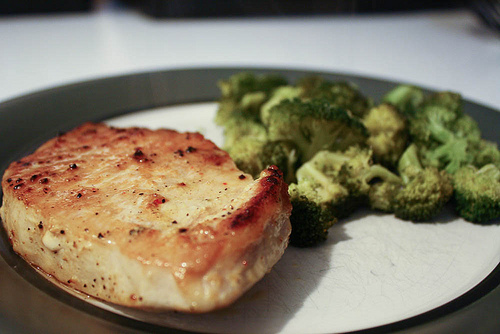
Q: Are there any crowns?
A: Yes, there is a crown.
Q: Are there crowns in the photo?
A: Yes, there is a crown.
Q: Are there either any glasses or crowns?
A: Yes, there is a crown.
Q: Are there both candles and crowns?
A: No, there is a crown but no candles.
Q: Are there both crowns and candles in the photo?
A: No, there is a crown but no candles.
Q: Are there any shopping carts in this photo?
A: No, there are no shopping carts.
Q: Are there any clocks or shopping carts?
A: No, there are no shopping carts or clocks.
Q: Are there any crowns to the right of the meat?
A: Yes, there is a crown to the right of the meat.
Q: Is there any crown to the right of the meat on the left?
A: Yes, there is a crown to the right of the meat.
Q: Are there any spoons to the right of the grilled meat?
A: No, there is a crown to the right of the meat.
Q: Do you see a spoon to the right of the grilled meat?
A: No, there is a crown to the right of the meat.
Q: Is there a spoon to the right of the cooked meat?
A: No, there is a crown to the right of the meat.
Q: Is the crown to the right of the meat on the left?
A: Yes, the crown is to the right of the meat.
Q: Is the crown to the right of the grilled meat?
A: Yes, the crown is to the right of the meat.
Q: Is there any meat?
A: Yes, there is meat.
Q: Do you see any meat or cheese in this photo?
A: Yes, there is meat.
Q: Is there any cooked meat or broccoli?
A: Yes, there is cooked meat.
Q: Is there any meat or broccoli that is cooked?
A: Yes, the meat is cooked.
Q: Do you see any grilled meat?
A: Yes, there is grilled meat.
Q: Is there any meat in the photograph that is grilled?
A: Yes, there is meat that is grilled.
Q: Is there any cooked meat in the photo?
A: Yes, there is cooked meat.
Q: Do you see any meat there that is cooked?
A: Yes, there is meat that is cooked.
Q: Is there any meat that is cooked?
A: Yes, there is meat that is cooked.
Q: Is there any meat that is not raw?
A: Yes, there is cooked meat.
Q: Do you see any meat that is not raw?
A: Yes, there is cooked meat.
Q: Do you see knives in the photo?
A: No, there are no knives.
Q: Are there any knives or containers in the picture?
A: No, there are no knives or containers.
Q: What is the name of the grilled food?
A: The food is meat.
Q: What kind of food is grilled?
A: The food is meat.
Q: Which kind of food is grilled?
A: The food is meat.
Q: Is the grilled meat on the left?
A: Yes, the meat is on the left of the image.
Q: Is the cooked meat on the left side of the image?
A: Yes, the meat is on the left of the image.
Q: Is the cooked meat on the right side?
A: No, the meat is on the left of the image.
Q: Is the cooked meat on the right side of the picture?
A: No, the meat is on the left of the image.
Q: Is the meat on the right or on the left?
A: The meat is on the left of the image.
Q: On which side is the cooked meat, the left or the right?
A: The meat is on the left of the image.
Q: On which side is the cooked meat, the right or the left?
A: The meat is on the left of the image.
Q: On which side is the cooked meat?
A: The meat is on the left of the image.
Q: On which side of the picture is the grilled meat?
A: The meat is on the left of the image.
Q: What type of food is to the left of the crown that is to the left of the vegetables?
A: The food is meat.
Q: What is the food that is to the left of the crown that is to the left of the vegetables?
A: The food is meat.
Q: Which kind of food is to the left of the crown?
A: The food is meat.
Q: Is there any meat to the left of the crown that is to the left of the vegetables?
A: Yes, there is meat to the left of the crown.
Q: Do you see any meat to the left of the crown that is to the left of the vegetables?
A: Yes, there is meat to the left of the crown.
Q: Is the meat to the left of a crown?
A: Yes, the meat is to the left of a crown.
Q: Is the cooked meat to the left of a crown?
A: Yes, the meat is to the left of a crown.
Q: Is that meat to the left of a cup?
A: No, the meat is to the left of a crown.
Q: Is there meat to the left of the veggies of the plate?
A: Yes, there is meat to the left of the veggies.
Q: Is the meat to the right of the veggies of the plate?
A: No, the meat is to the left of the vegetables.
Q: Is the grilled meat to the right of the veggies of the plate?
A: No, the meat is to the left of the vegetables.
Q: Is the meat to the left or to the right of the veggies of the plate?
A: The meat is to the left of the veggies.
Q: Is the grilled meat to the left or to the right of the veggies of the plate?
A: The meat is to the left of the veggies.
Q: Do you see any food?
A: Yes, there is food.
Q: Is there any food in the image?
A: Yes, there is food.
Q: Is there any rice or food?
A: Yes, there is food.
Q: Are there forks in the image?
A: No, there are no forks.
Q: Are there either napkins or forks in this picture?
A: No, there are no forks or napkins.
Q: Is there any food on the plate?
A: Yes, there is food on the plate.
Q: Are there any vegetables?
A: Yes, there are vegetables.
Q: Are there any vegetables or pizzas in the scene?
A: Yes, there are vegetables.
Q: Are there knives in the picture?
A: No, there are no knives.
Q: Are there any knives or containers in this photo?
A: No, there are no knives or containers.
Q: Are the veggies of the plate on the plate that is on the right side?
A: Yes, the veggies are on the plate.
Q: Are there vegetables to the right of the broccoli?
A: Yes, there are vegetables to the right of the broccoli.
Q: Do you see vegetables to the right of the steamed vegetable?
A: Yes, there are vegetables to the right of the broccoli.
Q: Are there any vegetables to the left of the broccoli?
A: No, the vegetables are to the right of the broccoli.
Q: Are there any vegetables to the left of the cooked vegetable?
A: No, the vegetables are to the right of the broccoli.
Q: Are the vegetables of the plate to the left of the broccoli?
A: No, the vegetables are to the right of the broccoli.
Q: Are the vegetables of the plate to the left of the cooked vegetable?
A: No, the vegetables are to the right of the broccoli.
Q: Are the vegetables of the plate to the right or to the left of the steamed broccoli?
A: The vegetables are to the right of the broccoli.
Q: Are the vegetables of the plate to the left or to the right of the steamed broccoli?
A: The vegetables are to the right of the broccoli.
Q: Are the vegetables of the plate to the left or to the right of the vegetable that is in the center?
A: The vegetables are to the right of the broccoli.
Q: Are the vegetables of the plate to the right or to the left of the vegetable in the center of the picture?
A: The vegetables are to the right of the broccoli.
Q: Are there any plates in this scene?
A: Yes, there is a plate.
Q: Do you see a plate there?
A: Yes, there is a plate.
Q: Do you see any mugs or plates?
A: Yes, there is a plate.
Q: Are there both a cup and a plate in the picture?
A: No, there is a plate but no cups.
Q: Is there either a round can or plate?
A: Yes, there is a round plate.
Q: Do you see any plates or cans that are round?
A: Yes, the plate is round.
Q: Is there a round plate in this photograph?
A: Yes, there is a round plate.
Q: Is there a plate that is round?
A: Yes, there is a plate that is round.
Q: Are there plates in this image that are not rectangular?
A: Yes, there is a round plate.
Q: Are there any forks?
A: No, there are no forks.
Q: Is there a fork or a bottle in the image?
A: No, there are no forks or bottles.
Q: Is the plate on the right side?
A: Yes, the plate is on the right of the image.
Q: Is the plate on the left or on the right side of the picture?
A: The plate is on the right of the image.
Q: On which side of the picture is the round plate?
A: The plate is on the right of the image.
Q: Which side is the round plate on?
A: The plate is on the right of the image.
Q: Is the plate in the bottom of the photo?
A: Yes, the plate is in the bottom of the image.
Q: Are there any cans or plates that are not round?
A: No, there is a plate but it is round.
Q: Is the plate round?
A: Yes, the plate is round.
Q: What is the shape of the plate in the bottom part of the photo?
A: The plate is round.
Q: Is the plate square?
A: No, the plate is round.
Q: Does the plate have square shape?
A: No, the plate is round.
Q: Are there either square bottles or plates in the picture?
A: No, there is a plate but it is round.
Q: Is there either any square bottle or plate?
A: No, there is a plate but it is round.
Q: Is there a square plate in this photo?
A: No, there is a plate but it is round.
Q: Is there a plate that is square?
A: No, there is a plate but it is round.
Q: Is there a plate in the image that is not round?
A: No, there is a plate but it is round.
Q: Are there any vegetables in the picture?
A: Yes, there are vegetables.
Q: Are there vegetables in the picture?
A: Yes, there are vegetables.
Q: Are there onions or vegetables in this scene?
A: Yes, there are vegetables.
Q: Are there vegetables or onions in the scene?
A: Yes, there are vegetables.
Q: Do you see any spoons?
A: No, there are no spoons.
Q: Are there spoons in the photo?
A: No, there are no spoons.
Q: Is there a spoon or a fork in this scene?
A: No, there are no spoons or forks.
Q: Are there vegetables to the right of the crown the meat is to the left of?
A: Yes, there are vegetables to the right of the crown.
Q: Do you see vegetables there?
A: Yes, there are vegetables.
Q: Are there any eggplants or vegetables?
A: Yes, there are vegetables.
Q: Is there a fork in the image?
A: No, there are no forks.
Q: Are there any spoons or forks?
A: No, there are no forks or spoons.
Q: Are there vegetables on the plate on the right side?
A: Yes, there are vegetables on the plate.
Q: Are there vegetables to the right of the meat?
A: Yes, there are vegetables to the right of the meat.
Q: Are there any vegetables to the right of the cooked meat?
A: Yes, there are vegetables to the right of the meat.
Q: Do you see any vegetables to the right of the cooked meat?
A: Yes, there are vegetables to the right of the meat.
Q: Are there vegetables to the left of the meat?
A: No, the vegetables are to the right of the meat.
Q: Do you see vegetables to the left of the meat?
A: No, the vegetables are to the right of the meat.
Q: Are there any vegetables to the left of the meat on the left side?
A: No, the vegetables are to the right of the meat.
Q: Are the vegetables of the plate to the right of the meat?
A: Yes, the veggies are to the right of the meat.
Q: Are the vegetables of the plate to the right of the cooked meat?
A: Yes, the veggies are to the right of the meat.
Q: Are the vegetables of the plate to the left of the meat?
A: No, the vegetables are to the right of the meat.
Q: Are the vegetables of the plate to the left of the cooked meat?
A: No, the vegetables are to the right of the meat.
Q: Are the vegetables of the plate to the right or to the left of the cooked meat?
A: The vegetables are to the right of the meat.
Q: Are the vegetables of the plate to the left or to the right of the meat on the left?
A: The vegetables are to the right of the meat.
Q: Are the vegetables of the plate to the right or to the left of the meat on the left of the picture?
A: The vegetables are to the right of the meat.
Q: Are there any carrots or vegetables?
A: Yes, there are vegetables.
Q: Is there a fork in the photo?
A: No, there are no forks.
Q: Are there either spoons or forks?
A: No, there are no forks or spoons.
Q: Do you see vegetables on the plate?
A: Yes, there are vegetables on the plate.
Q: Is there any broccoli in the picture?
A: Yes, there is broccoli.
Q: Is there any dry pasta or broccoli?
A: Yes, there is dry broccoli.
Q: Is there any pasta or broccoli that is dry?
A: Yes, the broccoli is dry.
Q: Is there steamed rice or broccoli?
A: Yes, there is steamed broccoli.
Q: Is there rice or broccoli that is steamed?
A: Yes, the broccoli is steamed.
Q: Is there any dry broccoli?
A: Yes, there is dry broccoli.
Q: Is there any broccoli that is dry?
A: Yes, there is broccoli that is dry.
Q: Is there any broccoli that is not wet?
A: Yes, there is dry broccoli.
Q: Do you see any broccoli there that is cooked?
A: Yes, there is cooked broccoli.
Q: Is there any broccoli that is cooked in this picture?
A: Yes, there is cooked broccoli.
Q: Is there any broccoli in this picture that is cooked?
A: Yes, there is broccoli that is cooked.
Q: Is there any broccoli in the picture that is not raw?
A: Yes, there is cooked broccoli.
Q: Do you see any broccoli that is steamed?
A: Yes, there is steamed broccoli.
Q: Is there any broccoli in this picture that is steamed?
A: Yes, there is broccoli that is steamed.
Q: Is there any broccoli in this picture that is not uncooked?
A: Yes, there is steamed broccoli.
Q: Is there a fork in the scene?
A: No, there are no forks.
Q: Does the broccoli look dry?
A: Yes, the broccoli is dry.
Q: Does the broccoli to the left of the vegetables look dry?
A: Yes, the broccoli is dry.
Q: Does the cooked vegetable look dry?
A: Yes, the broccoli is dry.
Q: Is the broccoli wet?
A: No, the broccoli is dry.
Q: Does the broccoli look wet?
A: No, the broccoli is dry.